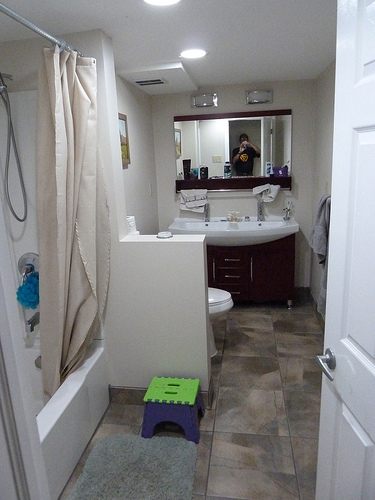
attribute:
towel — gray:
[301, 191, 332, 321]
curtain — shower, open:
[41, 44, 111, 375]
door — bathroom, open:
[313, 121, 353, 225]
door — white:
[312, 0, 374, 498]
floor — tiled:
[58, 290, 325, 498]